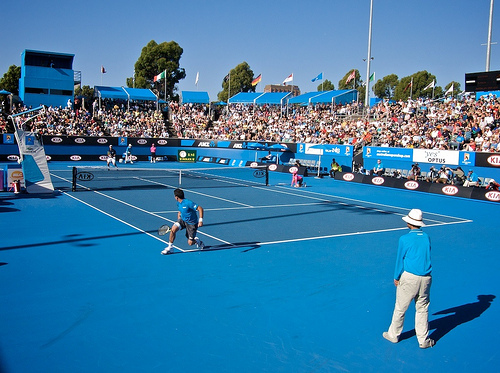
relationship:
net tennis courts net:
[68, 163, 270, 191] [62, 163, 272, 194]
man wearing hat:
[378, 206, 436, 349] [402, 211, 427, 225]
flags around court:
[97, 67, 463, 95] [3, 159, 498, 371]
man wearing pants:
[378, 206, 436, 349] [384, 270, 434, 348]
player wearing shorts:
[105, 143, 120, 172] [105, 154, 116, 164]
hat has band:
[400, 205, 427, 227] [405, 213, 423, 223]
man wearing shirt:
[378, 206, 436, 349] [394, 229, 432, 283]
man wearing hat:
[378, 206, 436, 349] [402, 209, 426, 236]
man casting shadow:
[378, 206, 436, 349] [395, 293, 495, 345]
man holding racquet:
[156, 187, 206, 255] [155, 223, 180, 238]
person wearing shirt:
[150, 143, 154, 166] [149, 143, 157, 153]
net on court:
[68, 163, 270, 191] [3, 159, 498, 371]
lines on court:
[35, 165, 471, 252] [3, 159, 498, 371]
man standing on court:
[390, 203, 442, 352] [164, 159, 376, 249]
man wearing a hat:
[378, 206, 436, 349] [401, 208, 427, 229]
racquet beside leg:
[157, 221, 170, 236] [161, 233, 178, 252]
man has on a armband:
[156, 187, 206, 255] [194, 216, 203, 224]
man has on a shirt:
[156, 187, 206, 255] [175, 203, 199, 219]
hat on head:
[403, 209, 427, 227] [401, 205, 429, 229]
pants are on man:
[388, 274, 433, 340] [390, 206, 437, 348]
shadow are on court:
[396, 294, 496, 345] [211, 176, 358, 281]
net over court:
[67, 168, 270, 188] [210, 176, 356, 262]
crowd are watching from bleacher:
[0, 91, 499, 157] [482, 165, 496, 179]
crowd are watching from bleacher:
[0, 91, 499, 157] [415, 144, 442, 163]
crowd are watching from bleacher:
[0, 91, 499, 157] [384, 144, 393, 162]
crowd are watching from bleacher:
[0, 91, 499, 157] [312, 150, 341, 166]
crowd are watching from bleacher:
[0, 91, 499, 157] [286, 143, 311, 153]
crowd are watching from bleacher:
[0, 91, 499, 157] [229, 135, 248, 158]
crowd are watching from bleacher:
[0, 91, 499, 157] [212, 140, 231, 149]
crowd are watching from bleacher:
[0, 91, 499, 157] [174, 134, 204, 151]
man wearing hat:
[378, 206, 436, 349] [399, 204, 434, 234]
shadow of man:
[418, 264, 497, 317] [388, 245, 431, 353]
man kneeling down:
[147, 171, 214, 259] [174, 239, 197, 249]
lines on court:
[51, 131, 455, 234] [6, 204, 464, 373]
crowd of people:
[2, 83, 498, 162] [57, 115, 457, 135]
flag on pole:
[144, 64, 176, 85] [161, 100, 167, 107]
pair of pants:
[381, 270, 432, 353] [400, 291, 430, 306]